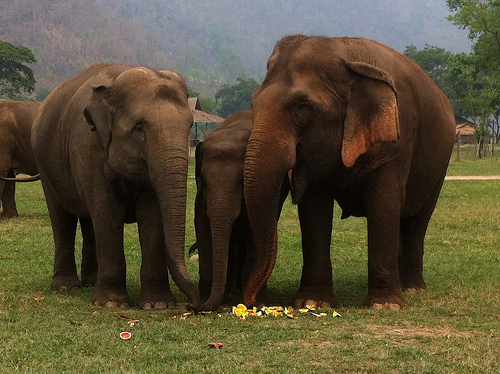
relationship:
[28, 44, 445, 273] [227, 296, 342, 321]
elephants snacking on oranges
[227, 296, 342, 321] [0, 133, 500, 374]
oranges on grass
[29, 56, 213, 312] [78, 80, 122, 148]
elephant with small ears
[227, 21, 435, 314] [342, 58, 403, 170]
elephant with two toned ears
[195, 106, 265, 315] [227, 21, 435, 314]
baby elephant by its mother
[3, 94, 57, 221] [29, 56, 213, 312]
elephant behind others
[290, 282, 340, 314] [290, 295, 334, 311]
elephant feet with toenails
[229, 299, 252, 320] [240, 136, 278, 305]
fruit tinted elephant trunk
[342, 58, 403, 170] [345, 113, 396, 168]
elephant ear with lighter edge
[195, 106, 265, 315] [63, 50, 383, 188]
small elephant between two bigger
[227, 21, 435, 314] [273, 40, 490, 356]
large elephant standing on right side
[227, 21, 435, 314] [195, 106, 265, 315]
large elephant standing directly to small elephant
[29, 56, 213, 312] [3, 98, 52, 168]
elephant in background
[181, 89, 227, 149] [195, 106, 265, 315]
small hut behind small elephant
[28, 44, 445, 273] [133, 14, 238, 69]
three elephants clearly visible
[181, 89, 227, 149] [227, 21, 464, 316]
small hut behind large elephant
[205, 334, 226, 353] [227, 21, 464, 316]
red circular in front of large elephant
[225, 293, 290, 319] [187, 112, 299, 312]
yellow debris in front of baby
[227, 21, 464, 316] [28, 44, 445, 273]
large elephant of bunch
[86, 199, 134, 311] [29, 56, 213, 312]
leg of an elephant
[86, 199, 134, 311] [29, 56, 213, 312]
leg if an elephant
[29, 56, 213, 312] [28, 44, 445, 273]
elephant an family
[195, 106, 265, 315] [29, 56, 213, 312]
baby a elephant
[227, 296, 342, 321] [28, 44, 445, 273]
food on ground for elephants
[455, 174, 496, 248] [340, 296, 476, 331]
large grassy area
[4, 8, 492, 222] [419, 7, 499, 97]
large area with many trees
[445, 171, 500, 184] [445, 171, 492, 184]
sidewalk or pathway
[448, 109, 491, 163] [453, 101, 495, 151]
shelter for people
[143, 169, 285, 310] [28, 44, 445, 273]
trunks of elephants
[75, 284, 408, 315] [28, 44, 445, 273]
feet of elephants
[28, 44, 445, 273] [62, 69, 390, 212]
three elephants facing forward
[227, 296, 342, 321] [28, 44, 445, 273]
fruit on ground for elephants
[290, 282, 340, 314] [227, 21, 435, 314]
front foot on elephant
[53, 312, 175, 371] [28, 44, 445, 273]
grass where are elephants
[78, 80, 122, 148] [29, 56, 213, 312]
ear of elephant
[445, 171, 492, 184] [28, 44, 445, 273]
sidewalk in back of elephants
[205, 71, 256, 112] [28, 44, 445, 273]
palm behind elephants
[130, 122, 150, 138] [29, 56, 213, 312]
eye of elephant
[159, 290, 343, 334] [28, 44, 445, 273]
fruit of elephants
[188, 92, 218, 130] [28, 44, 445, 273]
roof behind elephants